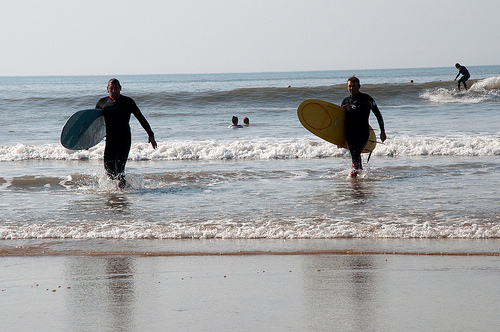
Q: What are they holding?
A: Surfboards.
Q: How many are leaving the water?
A: 2.